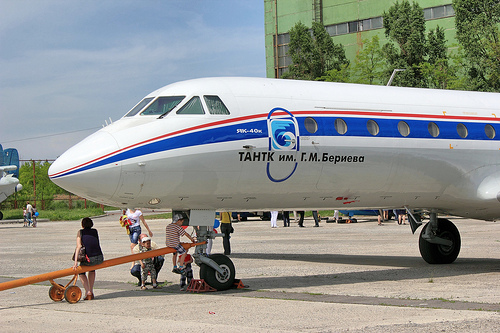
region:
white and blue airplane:
[17, 55, 496, 225]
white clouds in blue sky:
[22, 18, 89, 53]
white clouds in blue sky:
[13, 53, 42, 94]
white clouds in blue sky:
[21, 81, 74, 115]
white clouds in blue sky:
[100, 27, 157, 49]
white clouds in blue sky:
[37, 9, 92, 54]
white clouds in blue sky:
[18, 58, 70, 91]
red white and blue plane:
[0, 65, 491, 229]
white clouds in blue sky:
[200, 12, 230, 49]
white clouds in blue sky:
[124, 25, 171, 67]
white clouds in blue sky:
[45, 35, 66, 60]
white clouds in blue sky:
[74, 65, 129, 107]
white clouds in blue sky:
[1, 25, 72, 77]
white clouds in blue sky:
[57, 49, 107, 86]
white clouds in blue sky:
[7, 76, 62, 108]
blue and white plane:
[45, 61, 497, 245]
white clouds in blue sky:
[144, 21, 181, 51]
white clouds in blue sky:
[192, 18, 236, 58]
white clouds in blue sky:
[70, 18, 127, 59]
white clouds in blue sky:
[20, 21, 72, 92]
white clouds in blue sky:
[34, 76, 81, 113]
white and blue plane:
[12, 66, 496, 227]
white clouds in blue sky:
[22, 22, 79, 60]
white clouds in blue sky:
[12, 36, 42, 80]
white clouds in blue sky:
[94, 29, 138, 71]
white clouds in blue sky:
[25, 45, 76, 90]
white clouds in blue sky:
[54, 2, 89, 53]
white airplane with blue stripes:
[35, 73, 499, 295]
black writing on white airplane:
[237, 143, 369, 166]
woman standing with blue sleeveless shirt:
[72, 214, 110, 301]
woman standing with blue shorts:
[72, 213, 109, 305]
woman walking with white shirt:
[122, 209, 155, 262]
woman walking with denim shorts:
[118, 203, 154, 270]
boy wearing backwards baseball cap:
[163, 213, 193, 279]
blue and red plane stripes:
[38, 102, 491, 180]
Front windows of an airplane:
[125, 87, 233, 125]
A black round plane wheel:
[192, 245, 239, 291]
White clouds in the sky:
[0, 0, 270, 160]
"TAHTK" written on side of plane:
[230, 145, 275, 165]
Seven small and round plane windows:
[295, 107, 495, 147]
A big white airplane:
[40, 65, 496, 295]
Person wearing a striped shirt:
[155, 205, 200, 251]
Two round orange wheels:
[41, 277, 91, 307]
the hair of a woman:
[75, 214, 92, 230]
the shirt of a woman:
[77, 226, 106, 251]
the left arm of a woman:
[65, 232, 87, 257]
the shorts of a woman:
[75, 249, 107, 269]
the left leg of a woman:
[75, 266, 89, 291]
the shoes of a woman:
[81, 289, 98, 299]